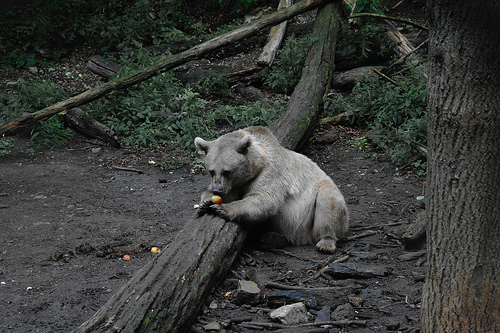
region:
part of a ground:
[111, 205, 145, 245]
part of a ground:
[353, 191, 394, 275]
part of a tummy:
[285, 197, 320, 240]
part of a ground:
[158, 233, 173, 255]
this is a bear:
[199, 120, 340, 242]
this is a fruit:
[206, 190, 223, 200]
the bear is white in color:
[288, 153, 295, 208]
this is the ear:
[238, 127, 254, 149]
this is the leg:
[231, 190, 261, 227]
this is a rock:
[262, 300, 307, 321]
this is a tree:
[302, 31, 366, 102]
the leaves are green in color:
[361, 80, 398, 121]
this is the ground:
[57, 155, 139, 244]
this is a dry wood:
[62, 74, 108, 105]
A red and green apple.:
[208, 192, 222, 205]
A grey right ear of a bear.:
[191, 136, 212, 155]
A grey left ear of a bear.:
[233, 135, 250, 153]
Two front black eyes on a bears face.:
[206, 167, 233, 177]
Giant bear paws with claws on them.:
[196, 198, 232, 222]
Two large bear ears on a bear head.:
[191, 135, 254, 156]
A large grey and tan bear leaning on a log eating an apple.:
[193, 124, 348, 253]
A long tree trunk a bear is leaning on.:
[71, 0, 341, 332]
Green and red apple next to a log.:
[148, 244, 161, 255]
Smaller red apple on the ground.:
[121, 253, 133, 263]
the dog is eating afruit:
[196, 130, 333, 261]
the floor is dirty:
[46, 188, 131, 253]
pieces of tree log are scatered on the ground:
[239, 281, 386, 323]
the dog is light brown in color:
[224, 130, 341, 229]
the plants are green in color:
[133, 86, 269, 124]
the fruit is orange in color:
[207, 191, 237, 206]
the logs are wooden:
[259, 4, 336, 73]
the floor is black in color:
[14, 201, 82, 293]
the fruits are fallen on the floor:
[113, 233, 160, 260]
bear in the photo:
[158, 101, 376, 248]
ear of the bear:
[228, 131, 264, 158]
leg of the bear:
[310, 195, 355, 250]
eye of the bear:
[216, 160, 238, 185]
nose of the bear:
[201, 180, 238, 203]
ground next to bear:
[105, 199, 167, 244]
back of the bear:
[245, 115, 283, 152]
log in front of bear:
[152, 215, 255, 285]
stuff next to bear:
[246, 262, 329, 327]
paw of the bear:
[202, 196, 241, 233]